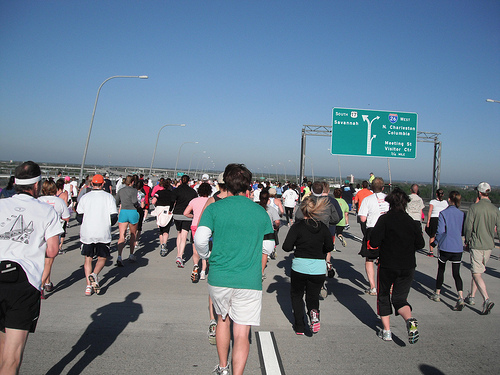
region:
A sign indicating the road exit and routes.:
[328, 104, 420, 159]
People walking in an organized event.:
[0, 158, 498, 374]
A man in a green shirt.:
[190, 160, 274, 372]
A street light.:
[78, 68, 149, 168]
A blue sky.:
[0, 0, 498, 106]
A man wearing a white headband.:
[7, 158, 42, 192]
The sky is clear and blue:
[2, 4, 495, 188]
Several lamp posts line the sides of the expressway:
[34, 38, 499, 177]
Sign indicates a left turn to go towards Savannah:
[331, 105, 421, 162]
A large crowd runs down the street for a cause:
[3, 131, 495, 370]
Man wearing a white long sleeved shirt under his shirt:
[178, 182, 291, 374]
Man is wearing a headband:
[10, 157, 50, 203]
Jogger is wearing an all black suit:
[368, 184, 443, 366]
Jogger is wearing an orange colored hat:
[70, 169, 127, 306]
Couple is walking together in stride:
[430, 161, 493, 327]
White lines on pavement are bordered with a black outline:
[248, 328, 289, 373]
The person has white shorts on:
[203, 275, 268, 332]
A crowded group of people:
[8, 145, 487, 347]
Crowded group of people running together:
[21, 169, 461, 314]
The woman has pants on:
[280, 267, 333, 340]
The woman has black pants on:
[282, 266, 337, 338]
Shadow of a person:
[80, 288, 172, 354]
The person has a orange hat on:
[83, 170, 111, 204]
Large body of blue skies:
[162, 17, 334, 92]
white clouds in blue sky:
[25, 13, 80, 55]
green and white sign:
[331, 98, 426, 160]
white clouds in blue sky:
[177, 38, 218, 79]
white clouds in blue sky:
[185, 95, 237, 129]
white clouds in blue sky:
[222, 13, 313, 85]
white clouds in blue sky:
[387, 19, 447, 61]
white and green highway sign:
[321, 101, 432, 162]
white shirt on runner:
[77, 192, 119, 237]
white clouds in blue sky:
[40, 29, 90, 71]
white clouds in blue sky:
[394, 13, 459, 53]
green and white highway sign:
[332, 85, 440, 175]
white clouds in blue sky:
[31, 9, 88, 81]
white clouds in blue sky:
[435, 42, 479, 107]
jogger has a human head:
[222, 162, 253, 197]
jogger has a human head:
[303, 197, 315, 217]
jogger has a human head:
[409, 182, 419, 192]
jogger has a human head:
[448, 188, 461, 205]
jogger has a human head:
[474, 182, 491, 199]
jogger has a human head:
[90, 173, 107, 185]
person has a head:
[224, 164, 253, 195]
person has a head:
[304, 201, 314, 221]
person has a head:
[308, 179, 325, 194]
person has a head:
[387, 188, 409, 213]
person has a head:
[370, 175, 382, 192]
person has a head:
[93, 171, 103, 190]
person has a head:
[14, 160, 42, 198]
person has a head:
[179, 174, 189, 184]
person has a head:
[198, 181, 211, 196]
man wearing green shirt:
[191, 162, 272, 374]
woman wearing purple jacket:
[432, 193, 465, 310]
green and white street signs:
[326, 109, 416, 161]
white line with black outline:
[257, 325, 284, 372]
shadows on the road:
[42, 213, 482, 373]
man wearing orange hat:
[77, 170, 127, 293]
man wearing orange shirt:
[348, 177, 371, 214]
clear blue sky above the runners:
[3, 2, 497, 183]